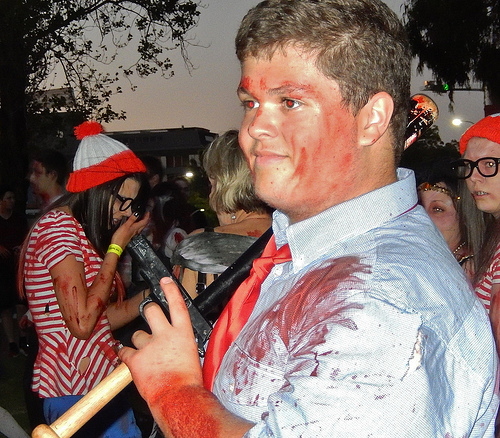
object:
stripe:
[38, 350, 78, 384]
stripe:
[42, 367, 66, 393]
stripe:
[40, 383, 52, 399]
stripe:
[35, 316, 61, 328]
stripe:
[24, 276, 54, 287]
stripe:
[471, 286, 493, 302]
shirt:
[471, 241, 497, 315]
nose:
[247, 111, 277, 141]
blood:
[279, 275, 332, 321]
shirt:
[210, 205, 496, 435]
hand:
[114, 272, 207, 399]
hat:
[55, 117, 143, 193]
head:
[66, 122, 143, 226]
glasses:
[110, 185, 138, 212]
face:
[103, 178, 137, 229]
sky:
[135, 74, 205, 112]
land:
[128, 123, 246, 202]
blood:
[293, 147, 311, 182]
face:
[232, 34, 377, 211]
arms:
[144, 388, 395, 438]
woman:
[18, 120, 140, 413]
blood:
[56, 276, 98, 331]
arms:
[39, 245, 143, 332]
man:
[111, 0, 499, 438]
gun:
[128, 237, 202, 362]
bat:
[58, 103, 438, 322]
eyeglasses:
[106, 183, 135, 209]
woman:
[445, 110, 497, 287]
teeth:
[472, 188, 486, 201]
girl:
[31, 122, 151, 426]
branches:
[42, 3, 179, 82]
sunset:
[113, 79, 197, 125]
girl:
[454, 117, 497, 322]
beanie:
[451, 109, 497, 142]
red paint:
[224, 62, 370, 212]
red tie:
[185, 235, 302, 389]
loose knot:
[243, 235, 292, 283]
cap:
[61, 117, 149, 190]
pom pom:
[74, 120, 104, 144]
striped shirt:
[12, 205, 142, 395]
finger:
[144, 283, 168, 332]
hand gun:
[120, 230, 223, 358]